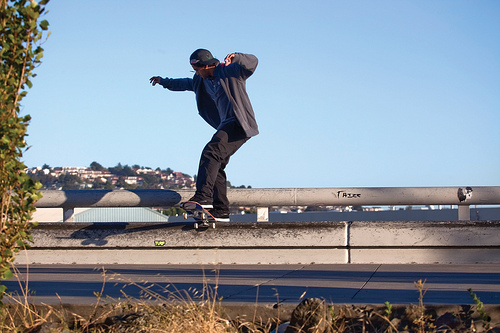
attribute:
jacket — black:
[168, 55, 268, 135]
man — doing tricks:
[145, 45, 262, 228]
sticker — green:
[143, 234, 170, 252]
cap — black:
[189, 49, 229, 81]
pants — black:
[180, 118, 262, 234]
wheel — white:
[181, 211, 189, 219]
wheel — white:
[192, 220, 200, 230]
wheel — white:
[199, 211, 206, 218]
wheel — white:
[210, 221, 217, 228]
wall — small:
[11, 218, 484, 268]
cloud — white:
[22, 81, 318, 186]